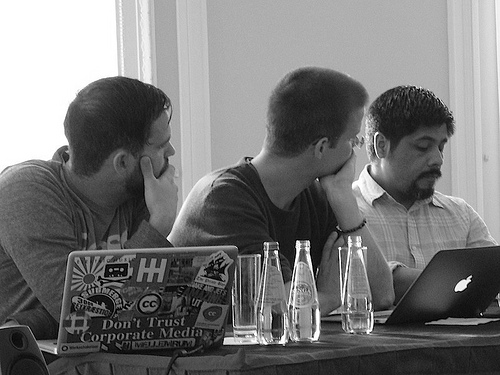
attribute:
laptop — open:
[322, 244, 498, 325]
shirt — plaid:
[351, 164, 500, 314]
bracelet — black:
[335, 217, 368, 238]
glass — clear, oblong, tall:
[231, 252, 265, 343]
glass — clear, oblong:
[337, 245, 368, 304]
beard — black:
[406, 181, 433, 200]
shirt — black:
[165, 155, 338, 328]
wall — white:
[117, 0, 499, 248]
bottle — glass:
[287, 240, 324, 344]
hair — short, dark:
[264, 66, 370, 161]